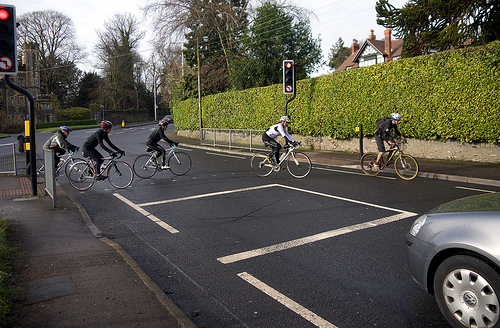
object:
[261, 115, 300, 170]
bicyclist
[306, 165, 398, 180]
lines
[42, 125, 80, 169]
cyclist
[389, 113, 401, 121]
helmet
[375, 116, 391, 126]
backpack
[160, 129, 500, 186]
sidewalk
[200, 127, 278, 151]
railing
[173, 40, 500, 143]
hedge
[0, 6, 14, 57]
light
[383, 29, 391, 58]
chimney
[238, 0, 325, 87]
trees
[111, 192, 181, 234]
lines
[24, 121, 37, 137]
object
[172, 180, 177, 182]
spots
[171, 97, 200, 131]
shrubbery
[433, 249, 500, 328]
tire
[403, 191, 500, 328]
car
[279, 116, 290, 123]
helmet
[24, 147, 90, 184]
bicycles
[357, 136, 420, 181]
bicycles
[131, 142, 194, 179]
bicycles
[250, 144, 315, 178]
bike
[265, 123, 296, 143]
shirt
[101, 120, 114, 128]
helmet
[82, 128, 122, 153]
shirt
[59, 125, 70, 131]
helmet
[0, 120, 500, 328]
road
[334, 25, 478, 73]
building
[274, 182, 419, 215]
marks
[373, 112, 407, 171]
cyclist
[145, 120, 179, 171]
cyclist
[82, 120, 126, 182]
cyclist